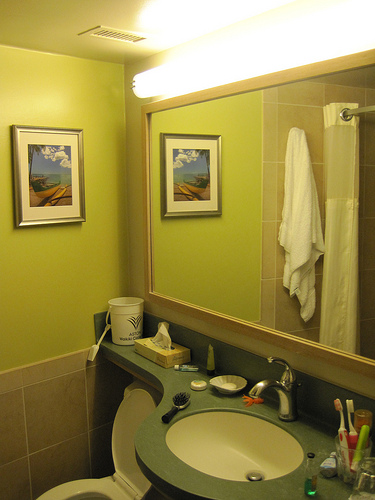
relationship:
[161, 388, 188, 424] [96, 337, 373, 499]
brush on counter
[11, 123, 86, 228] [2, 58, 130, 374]
picture on wall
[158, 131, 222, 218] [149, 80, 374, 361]
picture on wall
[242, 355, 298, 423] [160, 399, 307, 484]
faucet near sink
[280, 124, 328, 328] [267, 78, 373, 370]
towel hanging in shower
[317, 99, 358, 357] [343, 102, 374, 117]
shower curtain on rod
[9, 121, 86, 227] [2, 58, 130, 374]
frame on wall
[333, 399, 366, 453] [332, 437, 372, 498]
toothbrushes in drinking glass